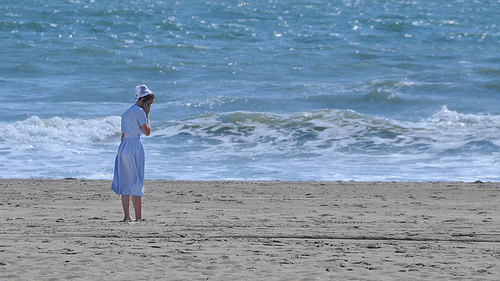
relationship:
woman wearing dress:
[111, 84, 155, 222] [112, 105, 148, 198]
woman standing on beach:
[111, 84, 155, 222] [0, 177, 499, 280]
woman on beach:
[111, 84, 155, 222] [0, 177, 499, 280]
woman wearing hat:
[111, 84, 155, 222] [135, 84, 154, 101]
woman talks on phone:
[111, 84, 155, 222] [141, 99, 150, 110]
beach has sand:
[0, 177, 499, 280] [56, 218, 63, 223]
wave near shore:
[0, 108, 499, 153] [0, 173, 499, 188]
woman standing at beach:
[111, 84, 155, 222] [0, 177, 499, 280]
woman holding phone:
[111, 84, 155, 222] [141, 99, 150, 110]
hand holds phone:
[142, 102, 150, 112] [141, 99, 150, 110]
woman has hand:
[111, 84, 155, 222] [142, 102, 150, 112]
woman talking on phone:
[111, 84, 155, 222] [141, 99, 150, 110]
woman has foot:
[111, 84, 155, 222] [134, 218, 143, 223]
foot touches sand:
[134, 218, 143, 223] [137, 219, 143, 223]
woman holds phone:
[111, 84, 155, 222] [141, 99, 150, 110]